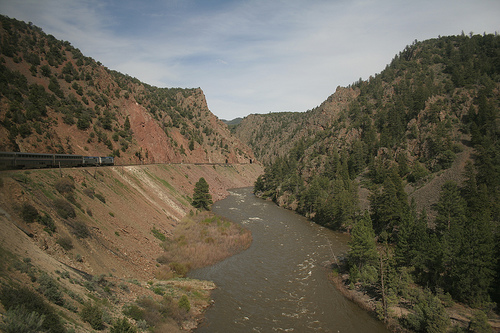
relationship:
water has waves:
[187, 184, 375, 312] [248, 216, 261, 223]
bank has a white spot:
[3, 165, 263, 311] [107, 167, 188, 225]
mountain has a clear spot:
[2, 13, 258, 161] [124, 104, 178, 164]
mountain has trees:
[2, 13, 258, 161] [1, 16, 139, 154]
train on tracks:
[1, 149, 114, 167] [2, 161, 260, 171]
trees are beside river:
[1, 16, 139, 154] [187, 183, 369, 311]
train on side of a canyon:
[1, 149, 114, 167] [4, 14, 268, 312]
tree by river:
[193, 177, 212, 210] [187, 183, 369, 311]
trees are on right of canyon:
[1, 16, 139, 154] [4, 14, 268, 312]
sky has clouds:
[1, 1, 499, 120] [0, 2, 499, 122]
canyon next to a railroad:
[4, 14, 268, 312] [1, 150, 112, 169]